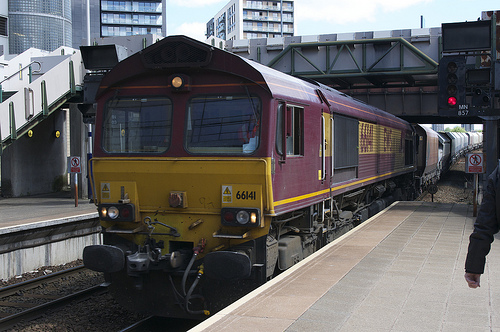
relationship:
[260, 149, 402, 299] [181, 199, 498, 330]
broadsection of train platform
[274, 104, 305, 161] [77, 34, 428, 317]
window on side of train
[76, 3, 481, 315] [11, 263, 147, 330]
train on track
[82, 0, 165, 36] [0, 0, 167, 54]
windows on building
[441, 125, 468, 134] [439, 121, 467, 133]
tree with leaves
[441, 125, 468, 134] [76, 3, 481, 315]
tree behind train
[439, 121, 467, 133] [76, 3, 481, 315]
leaves behind train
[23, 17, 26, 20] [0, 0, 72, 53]
window on a building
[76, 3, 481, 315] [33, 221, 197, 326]
train on track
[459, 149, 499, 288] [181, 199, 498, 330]
person on train platform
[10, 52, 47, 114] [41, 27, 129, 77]
strairs to walkway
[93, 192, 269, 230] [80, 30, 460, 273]
headlights in front of train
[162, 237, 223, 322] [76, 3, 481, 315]
cords in front of train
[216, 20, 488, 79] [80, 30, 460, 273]
walkway above train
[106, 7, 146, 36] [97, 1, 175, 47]
windows on building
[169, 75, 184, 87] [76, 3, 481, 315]
light on train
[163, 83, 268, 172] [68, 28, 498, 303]
windshield on train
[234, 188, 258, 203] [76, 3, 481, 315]
numbers on train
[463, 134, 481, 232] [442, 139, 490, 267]
arm of person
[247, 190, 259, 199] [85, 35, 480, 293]
4 on train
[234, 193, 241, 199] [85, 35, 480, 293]
number on train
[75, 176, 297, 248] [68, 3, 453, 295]
light on train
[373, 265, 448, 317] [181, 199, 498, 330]
stone tiles on train platform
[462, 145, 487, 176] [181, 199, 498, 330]
warning sign on train platform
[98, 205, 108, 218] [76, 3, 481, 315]
light on front of train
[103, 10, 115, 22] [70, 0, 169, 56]
window of building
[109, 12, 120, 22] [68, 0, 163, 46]
window on building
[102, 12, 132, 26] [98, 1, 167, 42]
window on building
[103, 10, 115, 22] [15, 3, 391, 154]
window on building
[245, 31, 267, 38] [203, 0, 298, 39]
window on building